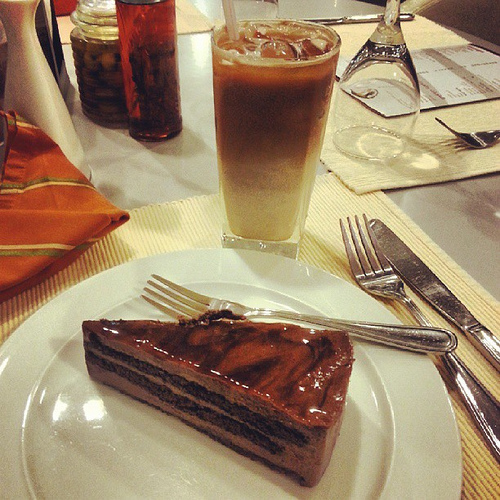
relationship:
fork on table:
[336, 210, 500, 465] [1, 1, 498, 500]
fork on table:
[433, 114, 500, 151] [1, 1, 498, 500]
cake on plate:
[81, 319, 354, 490] [1, 249, 463, 500]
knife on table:
[369, 217, 499, 372] [1, 1, 498, 500]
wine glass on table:
[333, 0, 423, 166] [1, 1, 498, 500]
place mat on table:
[1, 171, 500, 498] [1, 1, 498, 500]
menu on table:
[331, 42, 500, 121] [1, 1, 498, 500]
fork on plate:
[142, 271, 460, 357] [1, 249, 463, 500]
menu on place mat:
[331, 42, 500, 121] [322, 13, 500, 197]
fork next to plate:
[336, 210, 500, 465] [1, 249, 463, 500]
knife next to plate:
[369, 217, 499, 372] [1, 249, 463, 500]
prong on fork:
[140, 293, 189, 320] [142, 271, 460, 357]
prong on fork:
[147, 277, 209, 310] [142, 271, 460, 357]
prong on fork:
[150, 272, 215, 305] [142, 271, 460, 357]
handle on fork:
[254, 305, 459, 355] [142, 271, 460, 357]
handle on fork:
[402, 298, 500, 463] [336, 210, 500, 465]